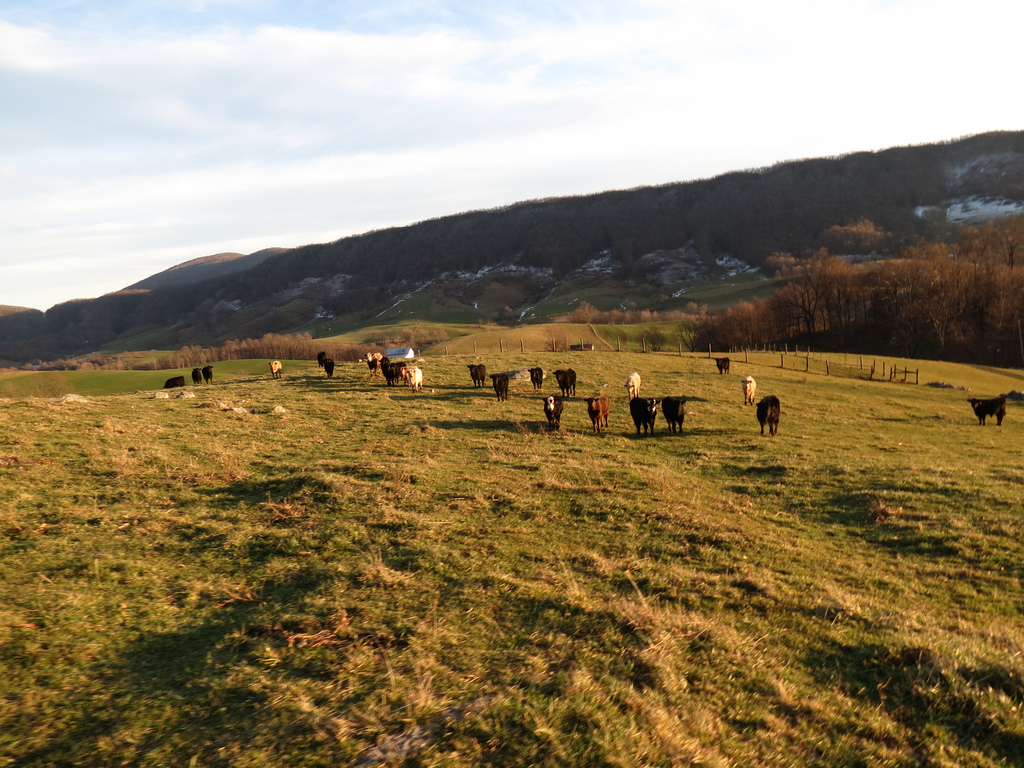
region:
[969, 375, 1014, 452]
a cow is by itself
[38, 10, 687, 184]
clouds mostly obscuring the sky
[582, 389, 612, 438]
a chestnut brown cow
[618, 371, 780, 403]
light colored cows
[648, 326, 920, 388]
fence in the background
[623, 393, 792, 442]
very dark cows in the field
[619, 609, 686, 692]
some clumps of grass are dry and brown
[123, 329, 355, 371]
a line of tall brush in the distance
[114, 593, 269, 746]
shadows falling across the grass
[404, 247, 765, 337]
patches of snow on a hill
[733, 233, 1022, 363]
the trees appear to be bare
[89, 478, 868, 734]
Tufts of green and brown grass.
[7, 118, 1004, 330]
Rolling hills, with meager, or dry, vegetation showing.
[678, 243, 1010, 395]
Section of dense, dry, vegetation, including bare trees.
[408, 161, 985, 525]
Vegetation suggests summer is fading, or past.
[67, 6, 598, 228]
Sky is light blue with skimming white clouds.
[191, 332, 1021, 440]
Livestock scattered across field.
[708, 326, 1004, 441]
Fencing with wooden posts, in distance.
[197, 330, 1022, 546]
Fencing and land suggests area with animals on it curving gently downward.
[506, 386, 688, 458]
A quartet of cows shows brown one with white face, brown one, black one and black one with white face.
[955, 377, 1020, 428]
Lonely black cow, far left, facing, facing forward. .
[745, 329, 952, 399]
fence in a pasture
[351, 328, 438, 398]
white building behind cows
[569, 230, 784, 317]
snow just above the grass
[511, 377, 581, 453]
black cow with white head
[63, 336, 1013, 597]
herd of cows in large field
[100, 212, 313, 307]
shadow on the hillside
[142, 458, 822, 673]
dead and alive grass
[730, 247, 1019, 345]
large group of trees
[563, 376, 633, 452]
brown cow in grass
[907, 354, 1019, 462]
black cow all alone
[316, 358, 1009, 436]
cattle grazing in a pasture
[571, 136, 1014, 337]
hillside with snow on the slopes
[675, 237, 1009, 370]
treeline laying dormant in winter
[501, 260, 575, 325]
ravine for water to run down the hill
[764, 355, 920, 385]
small man made fence for the pasture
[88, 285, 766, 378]
shadow line from the hillside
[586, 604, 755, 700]
clumps of hay type grass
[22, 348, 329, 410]
green pasture below hill side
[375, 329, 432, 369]
white building structure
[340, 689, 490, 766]
manure pile from grazing pasture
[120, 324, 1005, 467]
Several cows stand in a field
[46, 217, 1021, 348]
a large hill behind the cows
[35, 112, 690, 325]
the day is sunny and partly cloudy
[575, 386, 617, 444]
one cow is a bright orange-brown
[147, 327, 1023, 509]
the cows appear to be adult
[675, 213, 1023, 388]
a stand of trees are to the side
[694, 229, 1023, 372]
the trees don't have leaves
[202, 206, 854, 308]
it looks like there is snow on the mountain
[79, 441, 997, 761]
the grass is green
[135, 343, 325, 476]
some of the cows eat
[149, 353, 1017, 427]
A herd of cows.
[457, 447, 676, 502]
A patch of yellow grass.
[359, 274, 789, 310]
The view of a hillside.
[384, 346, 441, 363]
A little white house.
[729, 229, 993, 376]
A group of trees.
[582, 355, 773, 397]
Two white young cows.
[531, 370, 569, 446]
A white faced brown cow.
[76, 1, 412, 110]
A cloudy blue sky.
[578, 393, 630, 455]
A reddish-brown cow.